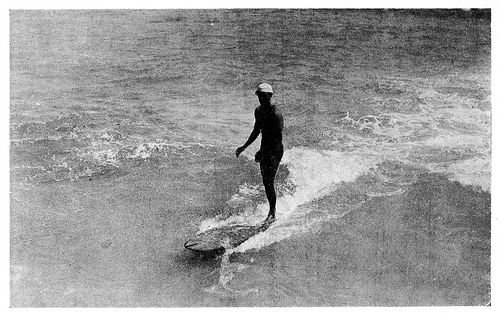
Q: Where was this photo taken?
A: At the beach.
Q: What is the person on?
A: A surfboard.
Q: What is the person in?
A: The ocean.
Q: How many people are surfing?
A: One.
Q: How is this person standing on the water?
A: On the surfboard.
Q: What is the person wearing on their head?
A: Swim cap.